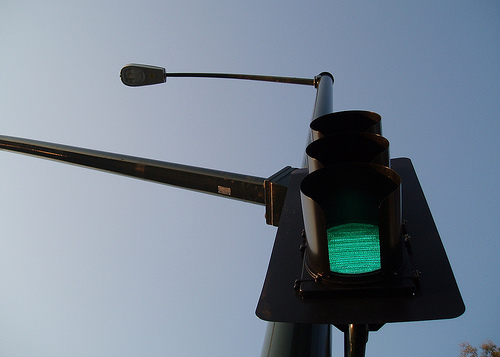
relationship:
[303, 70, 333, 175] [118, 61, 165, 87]
metal pole for lamp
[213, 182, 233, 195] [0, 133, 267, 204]
sticker on arm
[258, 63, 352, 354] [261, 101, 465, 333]
pole behind traffic signal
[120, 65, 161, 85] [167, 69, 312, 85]
bulb on arm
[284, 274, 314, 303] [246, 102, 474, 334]
bolt in traffic signal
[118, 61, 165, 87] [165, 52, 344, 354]
lamp on pole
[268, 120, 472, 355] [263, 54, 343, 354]
light on pole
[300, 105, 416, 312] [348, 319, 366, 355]
traffic light on pole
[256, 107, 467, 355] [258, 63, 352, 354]
light on pole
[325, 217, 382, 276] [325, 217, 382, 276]
bulb has bulb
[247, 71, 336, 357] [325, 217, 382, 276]
pole above bulb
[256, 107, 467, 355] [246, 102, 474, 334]
light in traffic signal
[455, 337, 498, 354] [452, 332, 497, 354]
leaves on tree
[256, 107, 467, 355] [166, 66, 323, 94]
light has arm